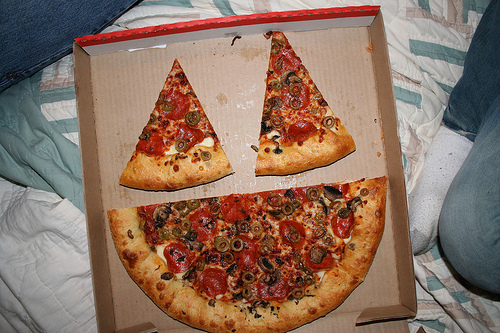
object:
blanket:
[0, 175, 96, 333]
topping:
[285, 226, 303, 245]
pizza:
[252, 31, 357, 178]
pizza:
[117, 56, 237, 193]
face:
[104, 29, 388, 333]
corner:
[70, 34, 96, 61]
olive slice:
[231, 237, 244, 252]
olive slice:
[214, 238, 230, 252]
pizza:
[105, 174, 389, 333]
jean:
[436, 0, 500, 295]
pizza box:
[70, 5, 420, 333]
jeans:
[0, 0, 145, 92]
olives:
[289, 96, 302, 111]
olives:
[185, 111, 201, 126]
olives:
[307, 187, 321, 201]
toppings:
[157, 227, 172, 241]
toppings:
[321, 235, 335, 248]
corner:
[365, 174, 390, 197]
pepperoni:
[162, 242, 195, 275]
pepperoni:
[220, 193, 250, 224]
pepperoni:
[279, 81, 311, 110]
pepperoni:
[175, 123, 206, 153]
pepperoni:
[196, 267, 230, 300]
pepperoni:
[254, 272, 289, 302]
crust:
[253, 126, 355, 177]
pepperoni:
[288, 120, 319, 143]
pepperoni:
[331, 208, 356, 240]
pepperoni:
[279, 219, 307, 250]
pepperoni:
[229, 234, 260, 270]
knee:
[435, 188, 499, 298]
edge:
[72, 2, 384, 52]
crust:
[117, 148, 239, 192]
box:
[69, 3, 421, 333]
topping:
[248, 223, 265, 237]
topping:
[220, 251, 237, 264]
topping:
[234, 220, 251, 233]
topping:
[179, 218, 193, 232]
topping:
[241, 270, 257, 284]